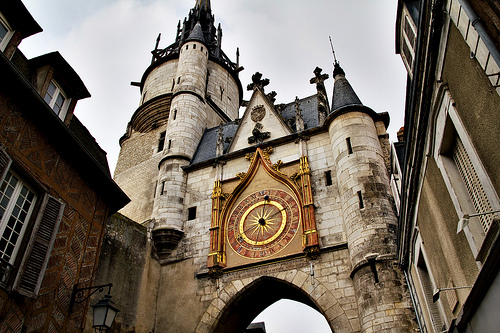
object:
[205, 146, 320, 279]
clock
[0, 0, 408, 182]
sky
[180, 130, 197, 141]
stone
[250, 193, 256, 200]
numerals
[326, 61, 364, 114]
spire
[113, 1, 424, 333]
castle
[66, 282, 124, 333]
lamp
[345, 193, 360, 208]
bricks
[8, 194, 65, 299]
shutters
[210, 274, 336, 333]
entryway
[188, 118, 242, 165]
roof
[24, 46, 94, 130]
attic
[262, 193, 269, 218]
hands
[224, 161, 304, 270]
face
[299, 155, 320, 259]
edging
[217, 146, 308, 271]
arch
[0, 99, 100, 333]
side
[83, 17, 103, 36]
part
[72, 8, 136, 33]
cloud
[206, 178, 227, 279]
edge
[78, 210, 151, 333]
wall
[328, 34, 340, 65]
spike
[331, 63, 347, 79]
top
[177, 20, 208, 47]
spire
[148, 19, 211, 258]
tower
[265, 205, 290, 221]
hand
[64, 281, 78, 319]
pole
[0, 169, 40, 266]
frame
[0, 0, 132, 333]
building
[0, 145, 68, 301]
window